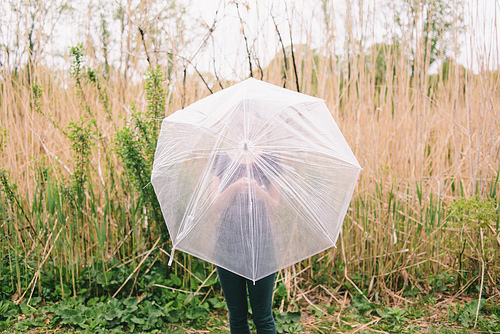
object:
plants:
[369, 185, 495, 332]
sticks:
[38, 251, 42, 298]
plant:
[0, 291, 179, 332]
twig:
[337, 289, 348, 319]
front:
[117, 76, 376, 325]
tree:
[392, 0, 466, 108]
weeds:
[55, 126, 143, 270]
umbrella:
[150, 77, 364, 285]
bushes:
[25, 88, 146, 298]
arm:
[209, 151, 243, 214]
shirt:
[209, 151, 283, 243]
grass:
[370, 94, 484, 313]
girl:
[202, 106, 286, 334]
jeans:
[217, 235, 279, 333]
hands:
[232, 177, 250, 192]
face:
[231, 108, 263, 141]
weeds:
[369, 278, 442, 326]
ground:
[0, 278, 500, 334]